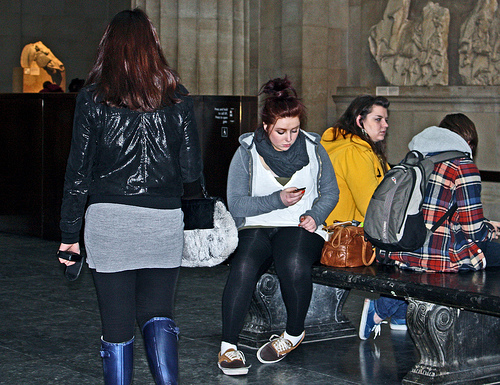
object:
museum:
[2, 1, 498, 385]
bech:
[220, 247, 499, 385]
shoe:
[143, 317, 181, 384]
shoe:
[99, 336, 135, 381]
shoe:
[359, 295, 380, 343]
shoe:
[392, 317, 408, 330]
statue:
[21, 43, 67, 73]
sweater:
[323, 128, 390, 232]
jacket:
[60, 76, 202, 243]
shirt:
[250, 133, 324, 228]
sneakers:
[255, 329, 308, 364]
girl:
[363, 111, 498, 281]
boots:
[104, 314, 181, 383]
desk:
[0, 89, 79, 236]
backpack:
[363, 149, 474, 251]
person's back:
[360, 130, 485, 280]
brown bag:
[319, 212, 374, 269]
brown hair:
[259, 75, 308, 126]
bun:
[256, 72, 296, 103]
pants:
[220, 217, 314, 344]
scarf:
[249, 133, 310, 171]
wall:
[250, 0, 377, 80]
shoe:
[256, 328, 309, 363]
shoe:
[216, 346, 250, 378]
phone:
[289, 189, 306, 197]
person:
[29, 11, 500, 385]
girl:
[217, 84, 343, 374]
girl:
[322, 91, 392, 227]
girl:
[58, 6, 203, 378]